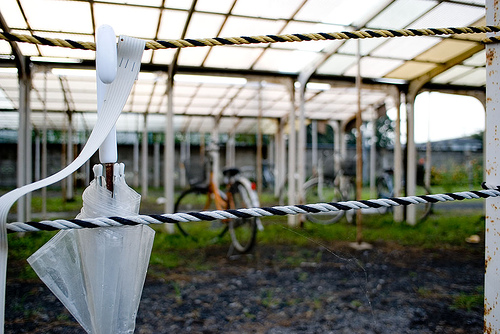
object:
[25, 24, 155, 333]
umbrella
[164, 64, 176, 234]
pole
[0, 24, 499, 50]
rope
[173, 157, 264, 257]
bicycle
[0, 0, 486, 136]
roof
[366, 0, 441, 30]
white panel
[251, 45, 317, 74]
white panel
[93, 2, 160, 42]
white panel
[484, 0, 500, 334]
rusty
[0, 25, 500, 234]
ropes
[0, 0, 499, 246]
structure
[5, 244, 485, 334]
dirt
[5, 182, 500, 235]
rope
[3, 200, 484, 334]
ground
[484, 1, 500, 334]
pole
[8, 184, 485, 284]
grass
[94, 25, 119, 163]
handle